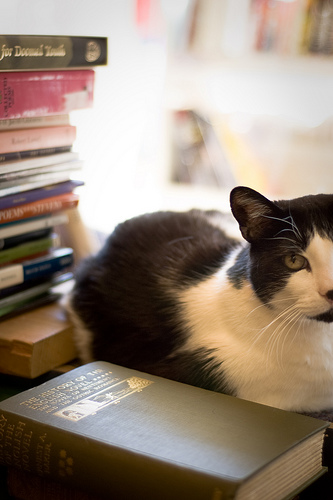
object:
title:
[21, 368, 155, 422]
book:
[0, 360, 331, 499]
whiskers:
[244, 294, 313, 362]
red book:
[1, 65, 97, 119]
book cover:
[0, 359, 329, 481]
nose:
[319, 281, 332, 300]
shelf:
[0, 375, 33, 391]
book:
[0, 34, 109, 319]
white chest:
[234, 300, 333, 413]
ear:
[228, 185, 285, 247]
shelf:
[150, 0, 327, 61]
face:
[255, 196, 332, 313]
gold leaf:
[127, 376, 153, 394]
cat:
[64, 184, 330, 422]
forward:
[4, 152, 331, 495]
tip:
[326, 287, 331, 297]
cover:
[0, 360, 331, 498]